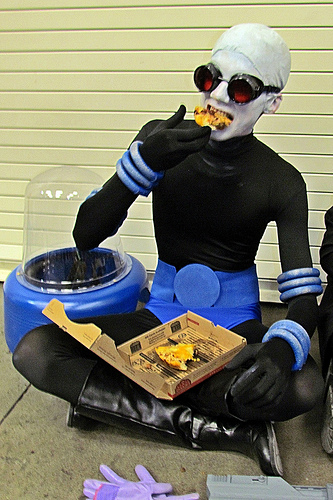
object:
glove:
[137, 103, 214, 176]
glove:
[223, 333, 298, 411]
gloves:
[66, 463, 200, 499]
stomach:
[165, 193, 241, 309]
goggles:
[191, 61, 281, 106]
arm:
[72, 118, 197, 256]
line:
[0, 1, 332, 12]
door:
[1, 1, 332, 305]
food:
[192, 103, 226, 128]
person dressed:
[192, 22, 292, 142]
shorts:
[144, 261, 260, 331]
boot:
[65, 354, 284, 479]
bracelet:
[113, 138, 160, 198]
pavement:
[24, 413, 119, 476]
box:
[39, 296, 248, 400]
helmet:
[2, 162, 149, 357]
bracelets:
[258, 315, 313, 369]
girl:
[12, 22, 322, 478]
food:
[153, 337, 204, 375]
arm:
[258, 158, 320, 352]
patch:
[19, 383, 114, 472]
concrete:
[0, 280, 333, 500]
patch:
[135, 448, 241, 471]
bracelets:
[275, 266, 324, 305]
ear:
[267, 92, 281, 113]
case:
[17, 165, 131, 295]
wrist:
[114, 143, 156, 200]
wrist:
[261, 318, 309, 371]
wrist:
[274, 268, 320, 302]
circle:
[171, 260, 221, 312]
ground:
[1, 282, 330, 496]